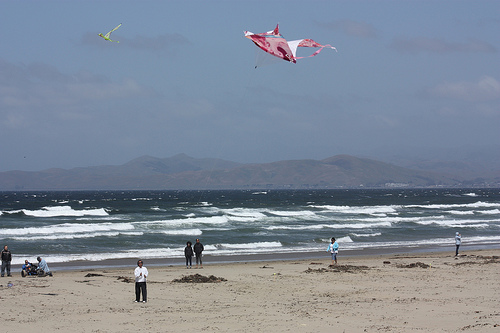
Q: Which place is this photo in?
A: It is at the ocean.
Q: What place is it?
A: It is an ocean.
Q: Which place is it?
A: It is an ocean.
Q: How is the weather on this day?
A: It is clear.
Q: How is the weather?
A: It is clear.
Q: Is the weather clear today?
A: Yes, it is clear.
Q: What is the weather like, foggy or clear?
A: It is clear.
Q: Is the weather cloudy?
A: No, it is clear.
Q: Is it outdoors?
A: Yes, it is outdoors.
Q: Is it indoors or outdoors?
A: It is outdoors.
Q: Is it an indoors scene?
A: No, it is outdoors.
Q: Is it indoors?
A: No, it is outdoors.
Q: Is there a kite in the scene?
A: Yes, there is a kite.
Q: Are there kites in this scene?
A: Yes, there is a kite.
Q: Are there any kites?
A: Yes, there is a kite.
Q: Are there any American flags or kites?
A: Yes, there is a kite.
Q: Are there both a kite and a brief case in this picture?
A: No, there is a kite but no briefcases.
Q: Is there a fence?
A: No, there are no fences.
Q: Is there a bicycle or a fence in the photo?
A: No, there are no fences or bicycles.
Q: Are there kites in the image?
A: Yes, there is a kite.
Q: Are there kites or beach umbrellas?
A: Yes, there is a kite.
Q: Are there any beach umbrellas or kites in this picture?
A: Yes, there is a kite.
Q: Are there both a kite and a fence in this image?
A: No, there is a kite but no fences.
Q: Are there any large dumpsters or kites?
A: Yes, there is a large kite.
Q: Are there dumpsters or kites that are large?
A: Yes, the kite is large.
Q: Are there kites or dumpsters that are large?
A: Yes, the kite is large.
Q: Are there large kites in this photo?
A: Yes, there is a large kite.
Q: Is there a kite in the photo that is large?
A: Yes, there is a kite that is large.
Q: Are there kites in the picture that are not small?
A: Yes, there is a large kite.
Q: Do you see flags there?
A: No, there are no flags.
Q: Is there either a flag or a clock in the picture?
A: No, there are no flags or clocks.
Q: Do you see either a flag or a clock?
A: No, there are no flags or clocks.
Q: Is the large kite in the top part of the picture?
A: Yes, the kite is in the top of the image.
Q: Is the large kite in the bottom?
A: No, the kite is in the top of the image.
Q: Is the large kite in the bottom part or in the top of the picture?
A: The kite is in the top of the image.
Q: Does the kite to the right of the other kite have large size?
A: Yes, the kite is large.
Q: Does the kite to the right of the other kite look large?
A: Yes, the kite is large.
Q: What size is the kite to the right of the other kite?
A: The kite is large.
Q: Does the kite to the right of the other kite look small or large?
A: The kite is large.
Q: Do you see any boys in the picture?
A: No, there are no boys.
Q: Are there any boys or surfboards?
A: No, there are no boys or surfboards.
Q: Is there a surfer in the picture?
A: No, there are no surfers.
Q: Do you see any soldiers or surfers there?
A: No, there are no surfers or soldiers.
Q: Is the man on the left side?
A: Yes, the man is on the left of the image.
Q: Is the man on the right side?
A: No, the man is on the left of the image.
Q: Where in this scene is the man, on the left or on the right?
A: The man is on the left of the image.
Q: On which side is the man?
A: The man is on the left of the image.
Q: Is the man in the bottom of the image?
A: Yes, the man is in the bottom of the image.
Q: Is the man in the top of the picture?
A: No, the man is in the bottom of the image.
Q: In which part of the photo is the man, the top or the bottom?
A: The man is in the bottom of the image.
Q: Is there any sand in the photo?
A: Yes, there is sand.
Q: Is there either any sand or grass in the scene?
A: Yes, there is sand.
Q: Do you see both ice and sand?
A: No, there is sand but no ice.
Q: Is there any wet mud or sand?
A: Yes, there is wet sand.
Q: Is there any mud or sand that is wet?
A: Yes, the sand is wet.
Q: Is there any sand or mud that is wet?
A: Yes, the sand is wet.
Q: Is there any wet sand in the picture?
A: Yes, there is wet sand.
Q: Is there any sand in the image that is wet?
A: Yes, there is sand that is wet.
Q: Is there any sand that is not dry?
A: Yes, there is wet sand.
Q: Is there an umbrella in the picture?
A: No, there are no umbrellas.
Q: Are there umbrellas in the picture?
A: No, there are no umbrellas.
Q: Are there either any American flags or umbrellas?
A: No, there are no umbrellas or American flags.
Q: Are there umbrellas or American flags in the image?
A: No, there are no umbrellas or American flags.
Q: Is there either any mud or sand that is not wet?
A: No, there is sand but it is wet.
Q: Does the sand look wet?
A: Yes, the sand is wet.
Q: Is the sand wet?
A: Yes, the sand is wet.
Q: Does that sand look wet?
A: Yes, the sand is wet.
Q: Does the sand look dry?
A: No, the sand is wet.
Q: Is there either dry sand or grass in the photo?
A: No, there is sand but it is wet.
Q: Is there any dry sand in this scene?
A: No, there is sand but it is wet.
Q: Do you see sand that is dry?
A: No, there is sand but it is wet.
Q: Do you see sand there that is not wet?
A: No, there is sand but it is wet.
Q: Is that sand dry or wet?
A: The sand is wet.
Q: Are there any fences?
A: No, there are no fences.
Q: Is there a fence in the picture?
A: No, there are no fences.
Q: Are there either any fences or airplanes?
A: No, there are no fences or airplanes.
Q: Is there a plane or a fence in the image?
A: No, there are no fences or airplanes.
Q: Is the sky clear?
A: Yes, the sky is clear.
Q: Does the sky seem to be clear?
A: Yes, the sky is clear.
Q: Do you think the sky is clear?
A: Yes, the sky is clear.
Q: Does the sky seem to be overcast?
A: No, the sky is clear.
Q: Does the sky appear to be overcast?
A: No, the sky is clear.